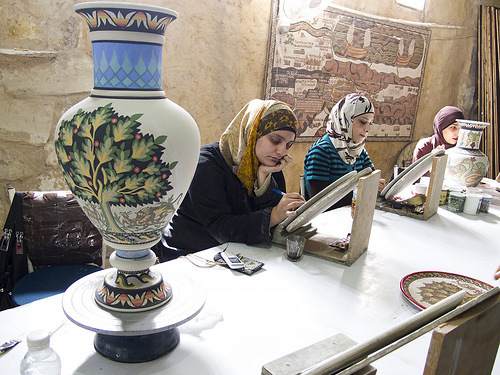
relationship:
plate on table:
[395, 268, 495, 318] [0, 174, 499, 374]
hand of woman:
[265, 190, 310, 230] [150, 92, 321, 264]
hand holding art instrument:
[265, 190, 310, 230] [270, 180, 291, 201]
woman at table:
[411, 105, 468, 175] [0, 174, 499, 374]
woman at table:
[150, 92, 321, 264] [0, 174, 499, 374]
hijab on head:
[216, 92, 303, 194] [251, 101, 302, 171]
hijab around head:
[322, 90, 380, 168] [333, 90, 380, 148]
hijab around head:
[430, 100, 468, 155] [430, 100, 467, 150]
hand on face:
[255, 152, 294, 180] [253, 125, 300, 169]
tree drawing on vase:
[48, 99, 181, 237] [47, 0, 206, 316]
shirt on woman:
[300, 130, 377, 201] [296, 89, 385, 213]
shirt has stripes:
[300, 130, 377, 201] [301, 132, 383, 184]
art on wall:
[258, 0, 437, 148] [2, 1, 500, 241]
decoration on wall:
[256, 0, 435, 146] [2, 1, 500, 241]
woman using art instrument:
[150, 92, 321, 264] [270, 189, 287, 197]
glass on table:
[284, 230, 311, 262] [0, 174, 499, 374]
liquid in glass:
[289, 251, 307, 260] [284, 230, 311, 262]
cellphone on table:
[221, 250, 249, 274] [0, 174, 499, 374]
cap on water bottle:
[25, 325, 55, 350] [17, 328, 63, 374]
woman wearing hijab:
[296, 89, 385, 213] [322, 90, 380, 168]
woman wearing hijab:
[150, 92, 321, 264] [216, 92, 303, 194]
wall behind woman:
[2, 1, 500, 241] [411, 105, 468, 175]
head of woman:
[251, 101, 302, 171] [150, 92, 321, 264]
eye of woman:
[264, 131, 286, 149] [150, 92, 321, 264]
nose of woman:
[271, 142, 288, 157] [150, 92, 321, 264]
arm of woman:
[188, 165, 276, 244] [150, 92, 321, 264]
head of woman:
[333, 90, 380, 148] [296, 89, 385, 213]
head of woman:
[430, 100, 467, 150] [411, 100, 469, 176]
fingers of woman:
[282, 191, 310, 223] [150, 92, 321, 264]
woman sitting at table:
[411, 105, 468, 175] [0, 174, 499, 374]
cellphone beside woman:
[221, 250, 249, 274] [150, 92, 321, 264]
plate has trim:
[395, 268, 495, 318] [398, 265, 497, 314]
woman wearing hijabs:
[411, 105, 468, 175] [213, 89, 471, 197]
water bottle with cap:
[17, 328, 63, 374] [25, 325, 55, 350]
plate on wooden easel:
[278, 164, 359, 236] [271, 162, 385, 271]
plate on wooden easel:
[383, 142, 435, 200] [378, 147, 449, 222]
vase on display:
[47, 0, 206, 316] [56, 262, 212, 364]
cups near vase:
[450, 190, 495, 221] [443, 117, 492, 190]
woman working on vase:
[411, 100, 469, 176] [443, 117, 492, 190]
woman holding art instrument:
[150, 92, 321, 264] [270, 180, 291, 201]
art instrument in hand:
[270, 180, 291, 201] [265, 190, 310, 230]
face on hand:
[253, 125, 300, 169] [255, 152, 294, 180]